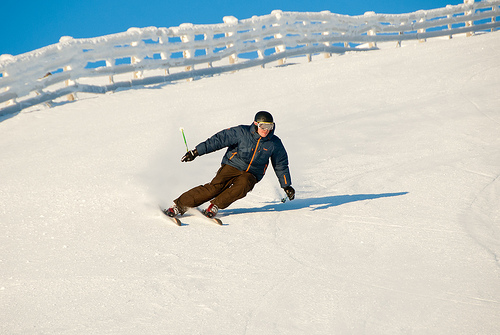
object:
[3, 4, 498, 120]
fence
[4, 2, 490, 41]
sky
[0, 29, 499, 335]
snow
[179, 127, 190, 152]
ski stick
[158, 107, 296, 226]
man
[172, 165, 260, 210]
pants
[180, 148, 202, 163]
gloves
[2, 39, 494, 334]
ground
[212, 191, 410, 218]
shadow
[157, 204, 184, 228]
ski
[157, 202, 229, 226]
two skis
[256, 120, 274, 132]
goggles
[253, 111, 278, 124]
helmet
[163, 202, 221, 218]
boots